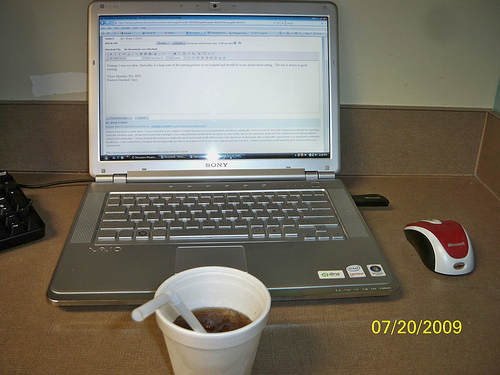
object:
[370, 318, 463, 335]
number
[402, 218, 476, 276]
mouse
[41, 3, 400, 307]
computer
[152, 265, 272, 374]
cup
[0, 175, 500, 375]
table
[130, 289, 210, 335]
straw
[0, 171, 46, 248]
keyboard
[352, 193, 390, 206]
usb drive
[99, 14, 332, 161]
screen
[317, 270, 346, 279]
sticker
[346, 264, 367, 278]
sticker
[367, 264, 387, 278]
sticker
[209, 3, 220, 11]
webcam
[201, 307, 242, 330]
ice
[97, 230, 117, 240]
button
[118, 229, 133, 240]
button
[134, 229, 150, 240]
button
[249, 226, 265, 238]
button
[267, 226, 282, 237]
button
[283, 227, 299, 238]
button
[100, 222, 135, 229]
button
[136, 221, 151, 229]
button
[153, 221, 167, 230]
button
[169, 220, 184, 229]
button